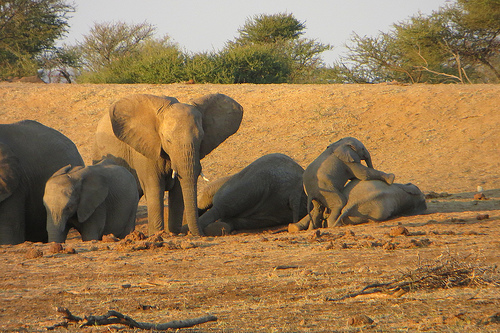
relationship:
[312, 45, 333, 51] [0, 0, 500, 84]
leaves on leaves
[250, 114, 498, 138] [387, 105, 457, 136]
dirt on side of hill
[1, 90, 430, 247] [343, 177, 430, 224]
herd of elephant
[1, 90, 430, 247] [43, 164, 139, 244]
herd of baby elephant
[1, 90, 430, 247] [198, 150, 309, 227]
herd of elephant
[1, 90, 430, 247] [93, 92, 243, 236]
herd of big elephant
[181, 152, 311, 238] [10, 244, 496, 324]
elephant laying in dirt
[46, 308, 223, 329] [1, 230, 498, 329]
branch on ground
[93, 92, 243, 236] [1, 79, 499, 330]
big elephant standing on dirt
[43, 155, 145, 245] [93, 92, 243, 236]
baby elephant taking shade from big elephant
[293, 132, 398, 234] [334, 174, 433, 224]
elephant on top of elephant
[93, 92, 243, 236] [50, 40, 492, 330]
big elephant standing in savannah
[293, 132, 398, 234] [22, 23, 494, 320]
elephant standing in savannah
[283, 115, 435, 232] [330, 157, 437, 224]
elephant climbing elephant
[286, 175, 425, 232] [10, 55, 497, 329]
elephant laying down in savannah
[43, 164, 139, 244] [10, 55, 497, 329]
baby elephant laying down in savannah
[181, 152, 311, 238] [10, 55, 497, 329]
elephant laying down in savannah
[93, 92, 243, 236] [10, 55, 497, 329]
big elephant laying down in savannah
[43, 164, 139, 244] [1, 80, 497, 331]
baby elephant laying down in savannah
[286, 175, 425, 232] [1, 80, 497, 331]
elephant laying down in savannah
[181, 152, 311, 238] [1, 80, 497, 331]
elephant laying down in savannah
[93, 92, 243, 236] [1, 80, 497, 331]
big elephant laying down in savannah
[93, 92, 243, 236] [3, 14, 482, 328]
big elephant standing in savannah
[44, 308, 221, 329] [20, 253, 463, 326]
branch on ground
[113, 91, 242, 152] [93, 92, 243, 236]
ears of an big elephant